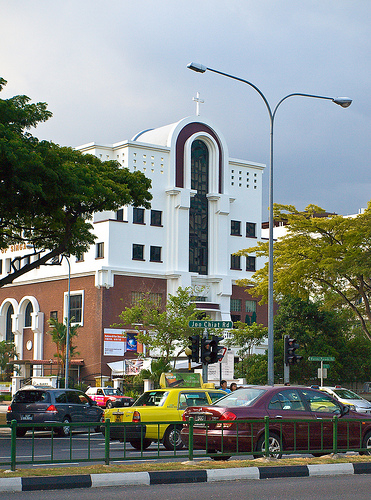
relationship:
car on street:
[184, 379, 367, 456] [0, 368, 369, 456]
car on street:
[108, 385, 246, 447] [0, 368, 369, 456]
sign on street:
[192, 314, 241, 334] [0, 368, 369, 456]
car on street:
[108, 385, 246, 447] [0, 402, 371, 471]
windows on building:
[128, 212, 267, 273] [1, 114, 294, 388]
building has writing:
[1, 114, 294, 388] [0, 225, 40, 258]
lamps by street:
[183, 60, 212, 78] [0, 368, 369, 456]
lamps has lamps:
[183, 60, 212, 78] [175, 60, 361, 108]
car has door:
[184, 379, 367, 456] [278, 406, 312, 443]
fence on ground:
[0, 412, 371, 473] [0, 430, 370, 499]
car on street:
[99, 368, 230, 451] [0, 368, 369, 456]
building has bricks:
[1, 114, 294, 388] [0, 281, 275, 391]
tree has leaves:
[262, 211, 370, 386] [284, 232, 330, 294]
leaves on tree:
[19, 163, 83, 202] [0, 78, 149, 325]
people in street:
[219, 377, 246, 395] [0, 368, 369, 456]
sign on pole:
[192, 314, 241, 334] [199, 326, 207, 389]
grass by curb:
[0, 452, 367, 480] [8, 454, 368, 489]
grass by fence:
[0, 452, 367, 480] [7, 412, 370, 474]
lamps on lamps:
[175, 60, 361, 108] [183, 60, 212, 78]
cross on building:
[192, 90, 206, 110] [1, 114, 294, 388]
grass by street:
[0, 452, 367, 480] [0, 368, 369, 456]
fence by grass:
[7, 412, 370, 474] [0, 452, 367, 480]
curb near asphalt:
[8, 454, 368, 489] [2, 473, 368, 499]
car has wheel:
[184, 379, 367, 456] [250, 434, 288, 461]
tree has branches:
[0, 78, 149, 325] [0, 171, 105, 304]